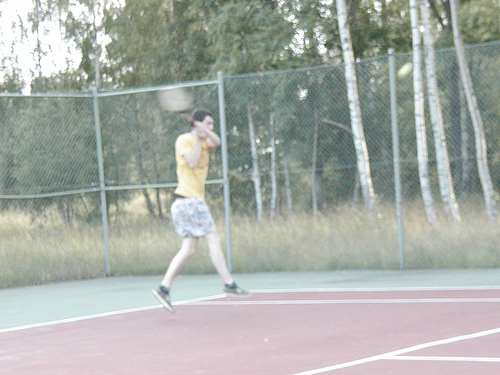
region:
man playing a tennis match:
[144, 102, 252, 315]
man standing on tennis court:
[138, 86, 256, 316]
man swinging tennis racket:
[151, 85, 200, 137]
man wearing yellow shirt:
[168, 125, 215, 200]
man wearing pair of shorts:
[161, 191, 218, 243]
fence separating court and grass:
[2, 37, 499, 280]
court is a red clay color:
[0, 275, 497, 374]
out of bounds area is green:
[1, 262, 498, 329]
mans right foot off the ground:
[150, 281, 174, 316]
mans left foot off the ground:
[222, 277, 252, 307]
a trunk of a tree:
[328, 6, 380, 211]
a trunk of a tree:
[407, 27, 437, 232]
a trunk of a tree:
[453, 28, 495, 238]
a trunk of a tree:
[245, 114, 267, 219]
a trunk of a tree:
[266, 112, 281, 224]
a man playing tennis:
[150, 89, 250, 304]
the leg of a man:
[160, 224, 200, 311]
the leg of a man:
[200, 225, 251, 296]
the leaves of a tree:
[162, 18, 219, 53]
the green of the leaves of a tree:
[44, 106, 86, 161]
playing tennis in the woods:
[156, 78, 478, 300]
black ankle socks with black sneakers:
[156, 276, 247, 301]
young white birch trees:
[328, 6, 496, 219]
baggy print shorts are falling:
[165, 186, 225, 236]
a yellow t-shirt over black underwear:
[176, 133, 212, 198]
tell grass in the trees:
[1, 201, 491, 276]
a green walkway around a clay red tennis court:
[0, 268, 497, 345]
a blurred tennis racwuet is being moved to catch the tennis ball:
[161, 81, 194, 126]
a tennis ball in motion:
[396, 48, 412, 80]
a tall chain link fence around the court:
[0, 38, 499, 277]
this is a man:
[119, 47, 276, 319]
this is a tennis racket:
[140, 53, 242, 167]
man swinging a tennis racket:
[145, 47, 272, 360]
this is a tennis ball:
[374, 38, 440, 118]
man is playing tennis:
[136, 44, 271, 336]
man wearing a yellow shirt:
[153, 107, 218, 212]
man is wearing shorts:
[155, 164, 232, 249]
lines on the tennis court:
[168, 280, 488, 374]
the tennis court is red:
[10, 242, 497, 372]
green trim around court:
[5, 222, 494, 327]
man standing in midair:
[143, 88, 257, 312]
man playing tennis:
[145, 84, 246, 307]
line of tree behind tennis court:
[4, 0, 494, 104]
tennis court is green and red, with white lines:
[1, 271, 489, 372]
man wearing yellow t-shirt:
[173, 130, 210, 199]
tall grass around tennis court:
[8, 208, 498, 270]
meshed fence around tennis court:
[6, 88, 142, 282]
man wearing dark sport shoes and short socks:
[147, 280, 254, 312]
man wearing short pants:
[170, 195, 220, 241]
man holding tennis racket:
[151, 88, 224, 163]